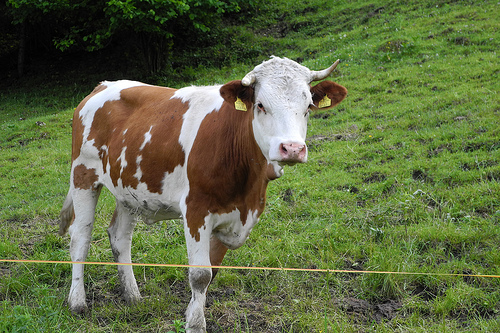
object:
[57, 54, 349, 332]
cow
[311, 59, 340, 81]
horns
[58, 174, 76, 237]
tail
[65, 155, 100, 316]
legs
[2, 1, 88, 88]
tree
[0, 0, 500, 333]
hill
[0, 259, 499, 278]
string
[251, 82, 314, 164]
face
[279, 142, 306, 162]
nose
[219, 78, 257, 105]
ear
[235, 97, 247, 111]
tag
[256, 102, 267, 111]
eyes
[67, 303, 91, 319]
foot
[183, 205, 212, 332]
front leg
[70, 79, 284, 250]
body